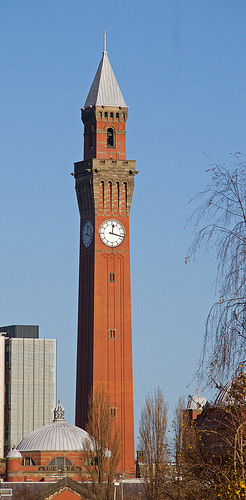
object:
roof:
[79, 37, 128, 111]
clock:
[99, 217, 126, 248]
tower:
[73, 29, 140, 478]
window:
[106, 127, 115, 149]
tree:
[142, 382, 167, 500]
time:
[99, 218, 125, 246]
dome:
[10, 422, 109, 452]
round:
[19, 417, 100, 456]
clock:
[81, 217, 94, 250]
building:
[0, 322, 58, 451]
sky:
[0, 0, 72, 320]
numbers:
[115, 221, 120, 227]